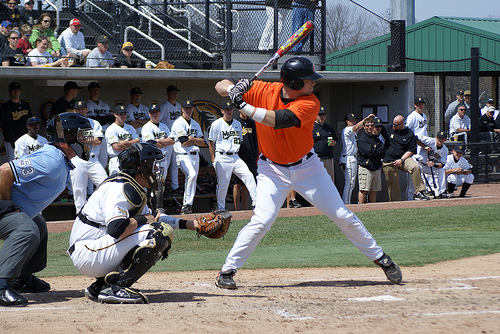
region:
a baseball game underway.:
[12, 12, 439, 317]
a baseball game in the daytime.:
[20, 13, 455, 310]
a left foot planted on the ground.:
[365, 246, 429, 293]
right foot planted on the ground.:
[205, 262, 255, 298]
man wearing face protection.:
[35, 111, 105, 173]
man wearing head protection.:
[271, 46, 326, 97]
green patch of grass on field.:
[392, 210, 472, 257]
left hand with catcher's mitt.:
[178, 205, 235, 245]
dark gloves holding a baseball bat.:
[226, 74, 254, 110]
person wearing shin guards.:
[109, 238, 181, 295]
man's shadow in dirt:
[270, 262, 418, 289]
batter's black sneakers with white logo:
[193, 255, 275, 302]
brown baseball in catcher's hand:
[190, 212, 243, 244]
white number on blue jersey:
[13, 151, 43, 186]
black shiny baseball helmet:
[278, 56, 325, 88]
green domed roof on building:
[349, 0, 497, 83]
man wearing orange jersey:
[233, 69, 346, 171]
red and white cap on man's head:
[62, 13, 99, 32]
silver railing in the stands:
[123, 22, 168, 61]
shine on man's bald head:
[390, 110, 419, 132]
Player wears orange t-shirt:
[198, 8, 413, 307]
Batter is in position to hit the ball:
[200, 10, 413, 317]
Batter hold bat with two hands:
[200, 11, 415, 303]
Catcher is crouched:
[56, 121, 238, 311]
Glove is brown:
[188, 196, 235, 243]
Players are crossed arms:
[61, 89, 212, 219]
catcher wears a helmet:
[53, 123, 240, 317]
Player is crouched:
[439, 134, 488, 204]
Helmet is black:
[276, 51, 328, 88]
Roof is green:
[321, 5, 498, 82]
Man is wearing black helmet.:
[273, 55, 326, 102]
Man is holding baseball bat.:
[216, 14, 318, 119]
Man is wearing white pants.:
[210, 148, 392, 280]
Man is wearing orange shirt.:
[229, 73, 326, 168]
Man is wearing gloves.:
[225, 73, 260, 111]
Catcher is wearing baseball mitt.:
[176, 202, 235, 251]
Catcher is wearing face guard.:
[137, 136, 171, 197]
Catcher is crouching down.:
[71, 132, 230, 315]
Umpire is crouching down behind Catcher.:
[0, 105, 95, 314]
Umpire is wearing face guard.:
[49, 110, 105, 165]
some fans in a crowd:
[4, 1, 146, 76]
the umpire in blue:
[0, 103, 93, 318]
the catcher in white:
[82, 130, 231, 314]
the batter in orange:
[211, 23, 414, 298]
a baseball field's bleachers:
[86, 5, 206, 60]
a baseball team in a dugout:
[7, 88, 426, 181]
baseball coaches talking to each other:
[313, 105, 424, 200]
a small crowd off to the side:
[447, 78, 497, 145]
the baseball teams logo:
[178, 91, 235, 158]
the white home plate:
[342, 280, 407, 318]